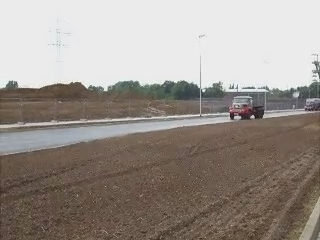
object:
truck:
[229, 96, 266, 120]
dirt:
[2, 113, 320, 239]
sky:
[2, 3, 320, 91]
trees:
[87, 79, 224, 100]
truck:
[304, 98, 320, 112]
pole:
[199, 55, 202, 118]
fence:
[0, 97, 319, 126]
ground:
[4, 88, 319, 238]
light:
[198, 34, 205, 117]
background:
[1, 69, 319, 123]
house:
[222, 89, 270, 111]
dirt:
[1, 82, 320, 128]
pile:
[41, 82, 88, 96]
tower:
[45, 23, 72, 88]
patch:
[6, 101, 212, 120]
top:
[220, 88, 269, 93]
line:
[105, 90, 219, 91]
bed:
[253, 104, 265, 113]